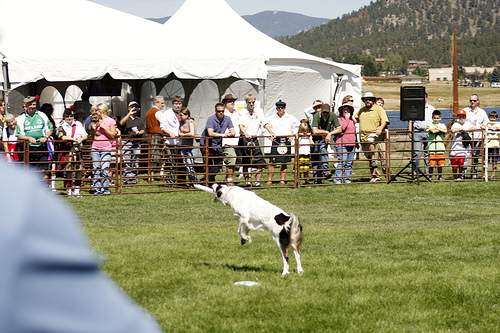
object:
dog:
[194, 178, 306, 274]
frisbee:
[195, 184, 219, 194]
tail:
[283, 208, 298, 239]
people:
[55, 91, 203, 125]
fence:
[111, 141, 164, 198]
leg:
[274, 244, 288, 276]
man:
[220, 87, 237, 162]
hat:
[272, 97, 281, 107]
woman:
[19, 93, 38, 107]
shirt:
[86, 131, 103, 142]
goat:
[206, 186, 251, 228]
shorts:
[429, 158, 446, 166]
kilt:
[370, 156, 394, 169]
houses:
[397, 51, 441, 81]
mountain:
[374, 12, 422, 29]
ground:
[189, 289, 219, 311]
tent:
[127, 5, 228, 66]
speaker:
[400, 83, 428, 118]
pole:
[449, 53, 461, 102]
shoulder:
[1, 192, 83, 231]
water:
[391, 120, 399, 128]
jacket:
[211, 123, 222, 128]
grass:
[95, 213, 182, 259]